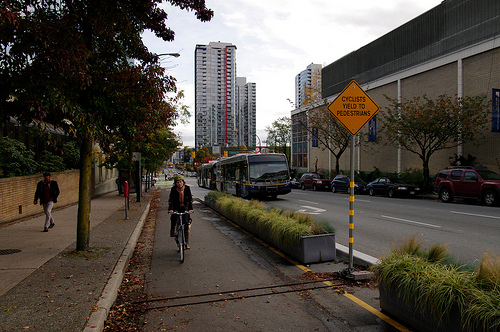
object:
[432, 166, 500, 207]
suv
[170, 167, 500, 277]
road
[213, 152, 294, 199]
bus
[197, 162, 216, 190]
bus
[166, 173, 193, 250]
woman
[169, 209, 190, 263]
bicycle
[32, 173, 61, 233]
man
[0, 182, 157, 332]
sidewalk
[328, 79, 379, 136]
sign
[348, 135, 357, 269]
pole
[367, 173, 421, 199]
car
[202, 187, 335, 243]
plants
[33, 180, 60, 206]
jacket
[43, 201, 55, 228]
pants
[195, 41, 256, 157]
building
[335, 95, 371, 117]
words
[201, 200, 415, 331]
line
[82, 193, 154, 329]
curb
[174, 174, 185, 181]
hat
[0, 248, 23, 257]
manhole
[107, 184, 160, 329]
leaves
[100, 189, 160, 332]
gutter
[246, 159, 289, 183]
windshield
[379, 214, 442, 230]
line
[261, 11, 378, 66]
clouds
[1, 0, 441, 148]
sky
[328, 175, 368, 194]
car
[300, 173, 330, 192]
car